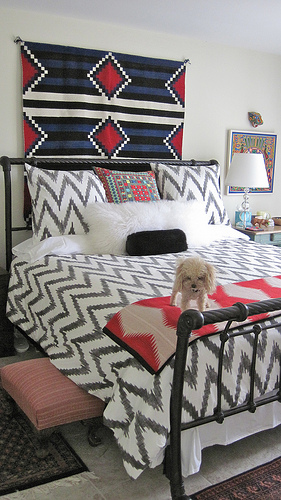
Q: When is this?
A: Daytime.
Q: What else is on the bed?
A: Pillow.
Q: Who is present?
A: No one.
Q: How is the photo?
A: Clear.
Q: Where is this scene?
A: In a bedroom.